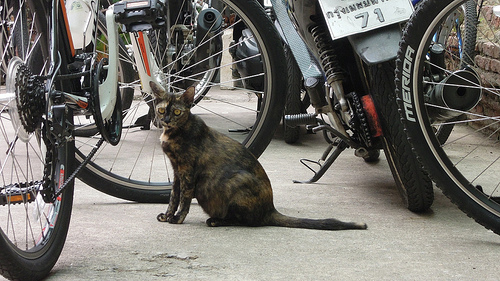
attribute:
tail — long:
[268, 202, 375, 241]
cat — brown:
[119, 75, 384, 251]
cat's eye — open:
[170, 106, 182, 117]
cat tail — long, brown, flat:
[270, 205, 369, 240]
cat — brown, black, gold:
[146, 84, 382, 234]